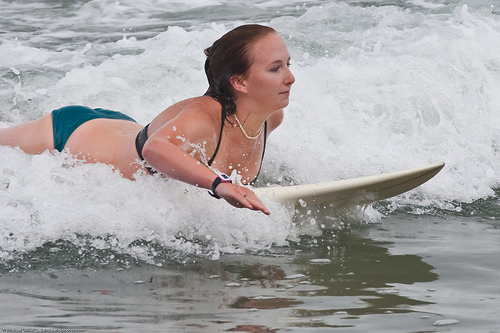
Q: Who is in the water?
A: A woman on a surfboard.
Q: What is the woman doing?
A: Surfing.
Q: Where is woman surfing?
A: In the ocean.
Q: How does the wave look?
A: Small and foamy.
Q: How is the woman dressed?
A: In a bikini.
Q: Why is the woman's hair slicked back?
A: It's wet.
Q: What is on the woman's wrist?
A: A watch.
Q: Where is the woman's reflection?
A: In the water.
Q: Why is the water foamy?
A: A wave crashed.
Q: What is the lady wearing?
A: Blue bikini trunks.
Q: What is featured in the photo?
A: The upper body of a female surfer.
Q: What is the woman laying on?
A: The white surfboard.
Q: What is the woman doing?
A: Riding the waves.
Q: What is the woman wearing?
A: A dark green bikini.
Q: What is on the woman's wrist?
A: A waterproof watch.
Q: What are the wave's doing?
A: Splashing.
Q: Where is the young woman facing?
A: Towards the beach.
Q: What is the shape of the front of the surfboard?
A: A rounded triangle.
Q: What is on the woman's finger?
A: A ring.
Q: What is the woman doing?
A: Paddling the surfboard.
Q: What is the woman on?
A: A surfboard.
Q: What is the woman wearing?
A: A bikini.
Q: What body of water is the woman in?
A: The ocean.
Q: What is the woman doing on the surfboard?
A: Lying on it.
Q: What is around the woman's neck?
A: A necklace.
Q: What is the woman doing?
A: Surfing.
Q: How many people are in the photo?
A: One.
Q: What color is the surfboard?
A: White.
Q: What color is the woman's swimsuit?
A: Blue.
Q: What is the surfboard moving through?
A: Waves.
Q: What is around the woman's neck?
A: Necklace.